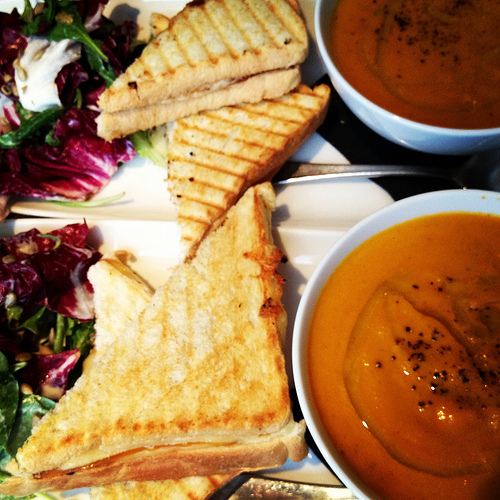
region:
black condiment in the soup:
[366, 273, 498, 439]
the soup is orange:
[301, 208, 498, 498]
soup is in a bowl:
[305, 211, 497, 498]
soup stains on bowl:
[473, 183, 495, 208]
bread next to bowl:
[1, 3, 321, 496]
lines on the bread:
[21, 6, 321, 478]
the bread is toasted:
[13, 3, 333, 488]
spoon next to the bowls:
[263, 128, 498, 213]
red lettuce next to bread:
[1, 0, 147, 452]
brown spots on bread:
[171, 137, 211, 199]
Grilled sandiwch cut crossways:
[95, 0, 309, 152]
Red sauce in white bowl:
[302, 192, 497, 495]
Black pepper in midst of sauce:
[369, 275, 496, 418]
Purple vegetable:
[15, 93, 152, 223]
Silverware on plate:
[273, 150, 447, 185]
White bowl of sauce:
[330, 83, 495, 173]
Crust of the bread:
[247, 183, 299, 449]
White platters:
[5, 136, 392, 282]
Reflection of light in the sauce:
[391, 362, 458, 432]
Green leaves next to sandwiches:
[0, 357, 48, 454]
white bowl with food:
[267, 199, 487, 445]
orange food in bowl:
[328, 286, 488, 408]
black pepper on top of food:
[338, 325, 483, 402]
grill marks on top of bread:
[21, 205, 278, 467]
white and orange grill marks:
[173, 297, 230, 357]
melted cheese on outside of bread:
[254, 253, 286, 317]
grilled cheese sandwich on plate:
[27, 178, 318, 484]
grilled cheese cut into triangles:
[74, 184, 289, 498]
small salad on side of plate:
[0, 41, 117, 141]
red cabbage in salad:
[0, 75, 128, 184]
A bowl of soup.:
[289, 189, 499, 499]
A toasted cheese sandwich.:
[0, 180, 306, 499]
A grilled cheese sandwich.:
[164, 78, 331, 258]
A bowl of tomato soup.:
[308, 2, 499, 158]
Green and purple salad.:
[0, 219, 102, 486]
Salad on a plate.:
[0, 1, 167, 216]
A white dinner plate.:
[269, 130, 395, 385]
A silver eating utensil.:
[273, 156, 498, 189]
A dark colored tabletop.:
[306, 70, 496, 166]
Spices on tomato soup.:
[372, 271, 499, 426]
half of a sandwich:
[94, 0, 304, 142]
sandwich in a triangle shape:
[10, 186, 300, 492]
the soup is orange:
[307, 210, 499, 497]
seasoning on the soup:
[372, 275, 498, 419]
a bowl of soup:
[312, 0, 498, 155]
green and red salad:
[0, 222, 95, 499]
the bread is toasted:
[20, 190, 309, 488]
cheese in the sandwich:
[35, 439, 236, 477]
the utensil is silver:
[279, 159, 441, 183]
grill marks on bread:
[110, 0, 303, 93]